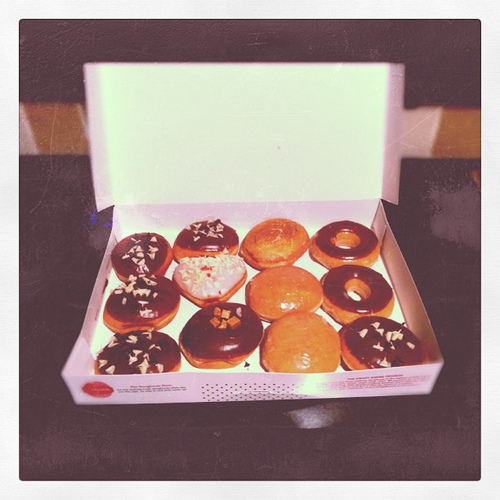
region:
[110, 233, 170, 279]
donut is next to donut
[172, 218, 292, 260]
donut is next to donut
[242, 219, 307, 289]
donut is next to donut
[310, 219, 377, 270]
donut is next to donut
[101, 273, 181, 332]
donut is next to donut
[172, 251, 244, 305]
donut is next to donut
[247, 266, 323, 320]
donut is next to donut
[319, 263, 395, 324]
donut is next to donut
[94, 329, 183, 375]
donut is next to donut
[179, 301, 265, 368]
donut is next to donut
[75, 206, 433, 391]
A box with a selection of donuts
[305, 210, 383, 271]
The donut is round.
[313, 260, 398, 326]
The donut is round.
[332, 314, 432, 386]
The donut is round.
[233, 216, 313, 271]
The donut is round.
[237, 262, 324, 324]
The donut is round.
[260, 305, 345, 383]
The donut is round.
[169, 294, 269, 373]
The donut is round.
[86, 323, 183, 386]
The donut is round.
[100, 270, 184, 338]
The donut is round.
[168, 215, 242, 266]
The donut is round.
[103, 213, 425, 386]
Dozen donuts in box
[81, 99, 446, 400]
White box filled with donuts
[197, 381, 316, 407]
Black dots on white box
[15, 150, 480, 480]
Black counter top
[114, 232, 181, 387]
Three donuts with toppings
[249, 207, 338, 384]
Three glazed donuts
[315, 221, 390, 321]
Two donuts without filling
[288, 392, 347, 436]
Light reflecting on counter top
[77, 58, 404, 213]
Lid of donut box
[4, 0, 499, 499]
White border along edges of picture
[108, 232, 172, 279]
donut next to donut in box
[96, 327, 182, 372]
donut next to donut in box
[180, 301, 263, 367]
donut next to donut in box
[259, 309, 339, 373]
donut next to donut in box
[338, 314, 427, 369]
donut next to donut in box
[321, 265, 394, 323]
donut next to donut in box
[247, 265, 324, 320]
donut next to donut in box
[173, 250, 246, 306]
donut next to donut in box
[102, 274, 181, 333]
donut next to donut in box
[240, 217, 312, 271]
donut next to donut in box